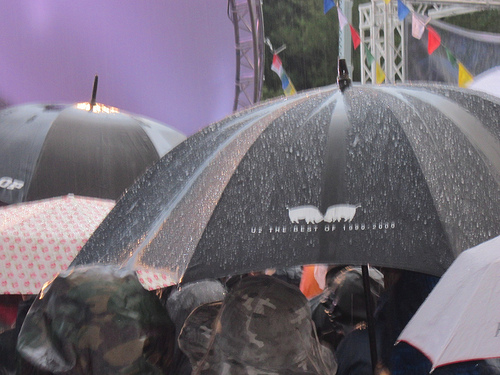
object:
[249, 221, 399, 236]
lettering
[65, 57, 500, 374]
largest umbrella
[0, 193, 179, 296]
umbrella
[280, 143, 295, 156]
drops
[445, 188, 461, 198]
drops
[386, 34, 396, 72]
steel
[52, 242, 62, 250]
pattern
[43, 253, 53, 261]
pattern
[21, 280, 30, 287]
pattern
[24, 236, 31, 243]
pattern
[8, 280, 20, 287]
pattern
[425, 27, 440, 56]
red sheet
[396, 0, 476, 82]
line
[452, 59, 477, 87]
flags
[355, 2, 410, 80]
beams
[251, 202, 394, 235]
image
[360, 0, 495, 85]
structure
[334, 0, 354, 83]
structure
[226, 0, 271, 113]
structure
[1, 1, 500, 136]
stage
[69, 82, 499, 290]
material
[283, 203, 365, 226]
trademark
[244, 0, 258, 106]
rail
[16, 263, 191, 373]
cap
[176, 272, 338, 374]
people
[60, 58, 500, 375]
umbrella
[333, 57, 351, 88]
point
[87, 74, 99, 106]
point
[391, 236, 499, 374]
umbrella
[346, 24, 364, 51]
material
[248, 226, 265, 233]
word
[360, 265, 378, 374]
handle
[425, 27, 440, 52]
material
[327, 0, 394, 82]
string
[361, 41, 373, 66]
flag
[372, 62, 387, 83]
flag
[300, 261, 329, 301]
clothing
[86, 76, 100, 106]
stick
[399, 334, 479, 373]
trim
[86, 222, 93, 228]
pattern